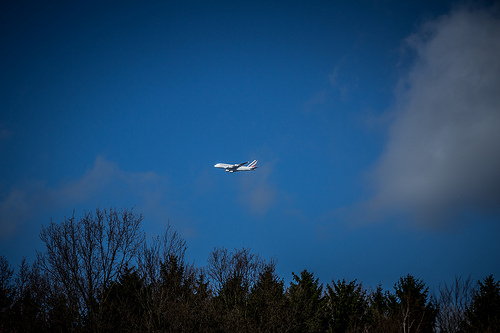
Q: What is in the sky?
A: A plane.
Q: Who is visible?
A: No one.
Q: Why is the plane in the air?
A: It is flying.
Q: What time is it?
A: Daytime.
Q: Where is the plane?
A: In the sky.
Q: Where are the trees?
A: Below the plane.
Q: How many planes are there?
A: One.